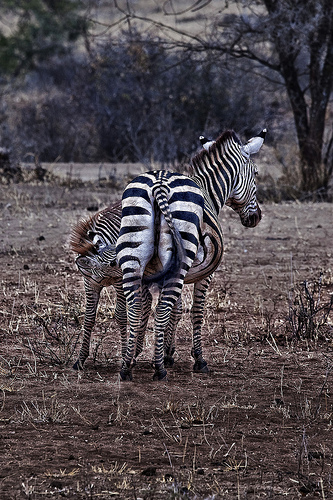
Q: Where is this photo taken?
A: The wild.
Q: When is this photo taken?
A: Daytime.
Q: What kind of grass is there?
A: Dead.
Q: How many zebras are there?
A: Two.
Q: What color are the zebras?
A: Black and white.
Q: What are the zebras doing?
A: Standing.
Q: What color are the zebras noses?
A: Black.